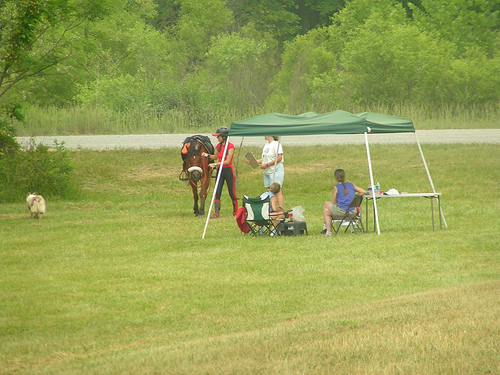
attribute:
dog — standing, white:
[25, 193, 45, 217]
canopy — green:
[257, 117, 363, 127]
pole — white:
[366, 132, 370, 154]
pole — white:
[413, 133, 419, 143]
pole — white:
[278, 137, 283, 143]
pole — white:
[227, 138, 229, 149]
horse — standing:
[186, 133, 205, 212]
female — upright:
[212, 130, 231, 165]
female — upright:
[259, 133, 278, 168]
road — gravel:
[81, 131, 152, 150]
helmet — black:
[218, 128, 224, 136]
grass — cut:
[99, 202, 163, 243]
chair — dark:
[351, 201, 361, 209]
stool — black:
[283, 223, 303, 233]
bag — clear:
[294, 208, 302, 221]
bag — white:
[390, 190, 395, 195]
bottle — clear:
[377, 184, 381, 193]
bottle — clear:
[367, 185, 371, 195]